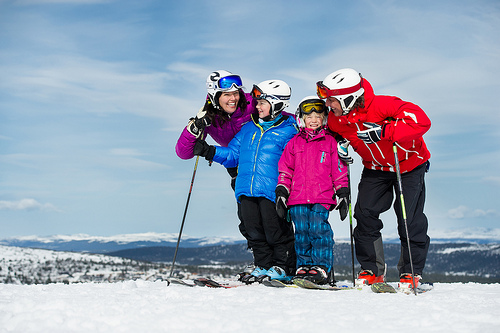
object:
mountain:
[2, 230, 118, 253]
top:
[0, 247, 464, 331]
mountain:
[106, 239, 493, 268]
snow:
[0, 237, 123, 269]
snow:
[0, 283, 500, 330]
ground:
[2, 281, 499, 331]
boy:
[193, 79, 300, 282]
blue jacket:
[214, 111, 302, 203]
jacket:
[328, 79, 432, 175]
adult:
[317, 67, 432, 288]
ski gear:
[316, 67, 432, 287]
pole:
[389, 138, 421, 295]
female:
[176, 68, 254, 253]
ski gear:
[176, 69, 256, 193]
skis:
[371, 279, 395, 293]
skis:
[408, 286, 435, 294]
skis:
[291, 276, 350, 291]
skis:
[263, 277, 293, 286]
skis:
[194, 277, 237, 289]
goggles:
[317, 81, 363, 100]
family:
[176, 68, 432, 288]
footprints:
[3, 288, 488, 330]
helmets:
[204, 70, 247, 109]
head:
[316, 67, 365, 117]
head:
[293, 96, 330, 132]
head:
[247, 76, 293, 119]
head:
[202, 68, 244, 115]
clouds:
[3, 0, 498, 225]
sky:
[3, 2, 497, 244]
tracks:
[75, 284, 485, 331]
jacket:
[175, 91, 257, 167]